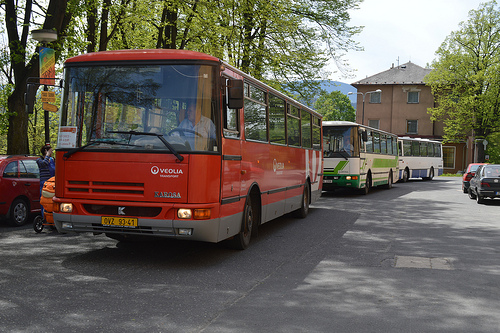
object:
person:
[33, 141, 58, 195]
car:
[0, 154, 45, 227]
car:
[466, 162, 499, 205]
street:
[0, 173, 499, 332]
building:
[349, 58, 475, 176]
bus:
[392, 135, 445, 185]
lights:
[175, 206, 191, 222]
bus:
[50, 47, 326, 251]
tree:
[422, 0, 500, 165]